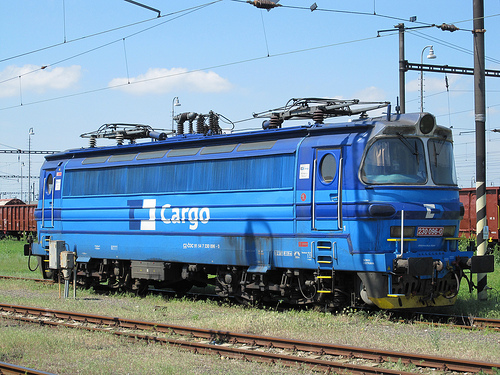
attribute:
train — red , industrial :
[459, 177, 499, 228]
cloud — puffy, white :
[102, 59, 236, 98]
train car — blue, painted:
[23, 109, 491, 308]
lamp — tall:
[422, 43, 442, 63]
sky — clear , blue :
[81, 42, 348, 84]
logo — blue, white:
[118, 192, 221, 240]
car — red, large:
[454, 182, 499, 244]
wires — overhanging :
[31, 12, 498, 162]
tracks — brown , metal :
[1, 300, 499, 374]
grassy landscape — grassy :
[32, 335, 134, 369]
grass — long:
[2, 235, 497, 373]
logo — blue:
[121, 193, 211, 229]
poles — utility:
[478, 0, 485, 301]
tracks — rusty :
[4, 289, 498, 373]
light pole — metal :
[412, 36, 444, 128]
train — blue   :
[28, 94, 463, 314]